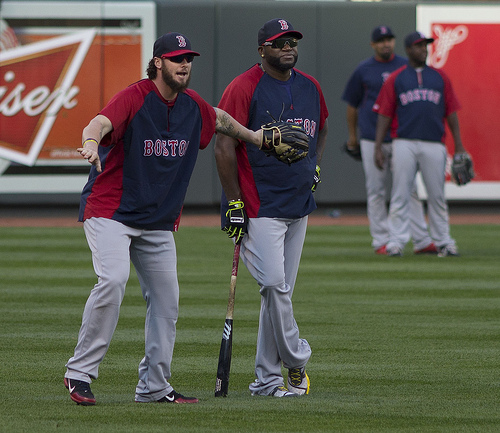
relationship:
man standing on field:
[66, 33, 308, 414] [1, 199, 497, 432]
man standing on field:
[216, 17, 340, 402] [1, 199, 497, 432]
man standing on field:
[375, 28, 474, 257] [1, 199, 497, 432]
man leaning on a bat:
[216, 17, 340, 402] [212, 226, 243, 398]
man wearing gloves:
[216, 17, 340, 402] [219, 201, 252, 243]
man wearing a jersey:
[66, 33, 308, 414] [91, 77, 217, 232]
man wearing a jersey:
[216, 17, 340, 402] [220, 61, 328, 223]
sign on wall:
[0, 1, 157, 191] [0, 1, 499, 204]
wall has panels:
[0, 1, 499, 204] [210, 5, 331, 211]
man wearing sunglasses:
[66, 33, 308, 414] [168, 55, 197, 64]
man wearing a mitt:
[66, 33, 308, 414] [254, 125, 310, 166]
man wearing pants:
[66, 33, 308, 414] [66, 214, 187, 399]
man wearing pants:
[216, 17, 340, 402] [233, 214, 314, 388]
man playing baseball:
[66, 33, 308, 414] [384, 278, 385, 280]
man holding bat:
[216, 17, 340, 402] [212, 226, 243, 398]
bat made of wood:
[212, 226, 243, 398] [230, 275, 242, 308]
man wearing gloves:
[66, 33, 308, 414] [219, 201, 252, 243]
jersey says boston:
[91, 77, 217, 232] [140, 133, 191, 164]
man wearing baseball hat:
[66, 33, 308, 414] [148, 32, 199, 65]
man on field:
[66, 33, 308, 414] [1, 199, 497, 432]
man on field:
[216, 17, 340, 402] [1, 199, 497, 432]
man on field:
[375, 28, 474, 257] [1, 199, 497, 432]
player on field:
[339, 26, 436, 263] [1, 199, 497, 432]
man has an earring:
[216, 17, 340, 402] [260, 50, 264, 59]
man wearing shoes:
[66, 33, 308, 414] [62, 367, 199, 405]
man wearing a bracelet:
[66, 33, 308, 414] [80, 137, 101, 148]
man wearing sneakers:
[216, 17, 340, 402] [248, 367, 319, 407]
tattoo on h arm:
[216, 114, 236, 135] [188, 92, 287, 163]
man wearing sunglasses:
[216, 17, 340, 402] [262, 40, 301, 50]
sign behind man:
[0, 1, 157, 191] [66, 33, 308, 414]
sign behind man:
[412, 10, 497, 198] [375, 28, 474, 257]